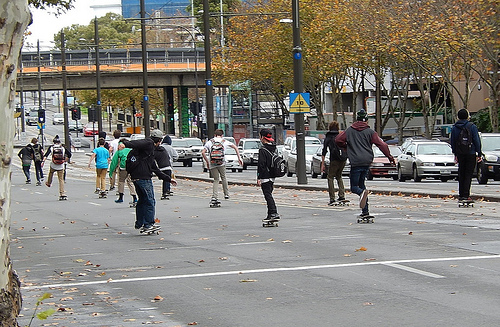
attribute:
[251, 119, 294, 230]
skateboarder — young 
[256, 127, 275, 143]
cap — black, red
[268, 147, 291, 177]
bag — black 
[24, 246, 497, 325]
lines — white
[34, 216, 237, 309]
leafs — scatterd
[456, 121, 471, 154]
backpack — black, white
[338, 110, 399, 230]
skateboarder — skating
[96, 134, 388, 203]
skateboarders — group 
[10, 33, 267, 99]
overpass — old 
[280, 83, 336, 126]
sign — blue , yellow 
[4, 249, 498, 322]
lines — white 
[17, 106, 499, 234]
people — group, skateboarding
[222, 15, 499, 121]
trees — yellow 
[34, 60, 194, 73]
bridge — overhead